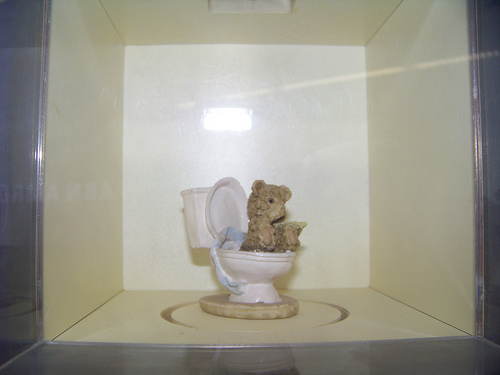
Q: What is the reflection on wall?
A: Light.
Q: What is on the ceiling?
A: Vent.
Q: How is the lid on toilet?
A: Open.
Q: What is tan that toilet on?
A: Base.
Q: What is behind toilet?
A: Tank.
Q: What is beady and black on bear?
A: Eyes.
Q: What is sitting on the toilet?
A: A teddy bear.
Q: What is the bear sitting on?
A: A miniature toilet.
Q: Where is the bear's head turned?
A: To the left.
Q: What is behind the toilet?
A: A white wall.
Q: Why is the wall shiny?
A: Light reflecting off it.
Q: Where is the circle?
A: Around the toilet.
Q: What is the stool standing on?
A: A platform.